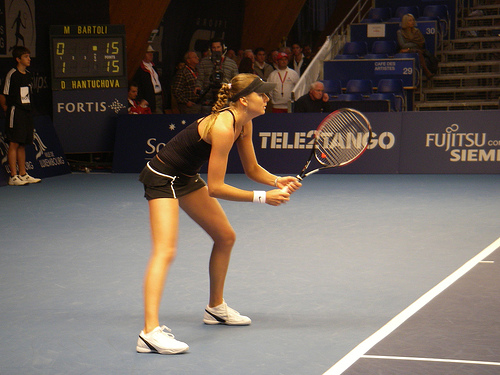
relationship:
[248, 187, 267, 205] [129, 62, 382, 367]
wrist band on player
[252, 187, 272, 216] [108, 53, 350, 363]
wrist band on player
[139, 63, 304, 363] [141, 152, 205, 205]
woman wearing shorts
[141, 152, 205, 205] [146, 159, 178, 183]
shorts with stripe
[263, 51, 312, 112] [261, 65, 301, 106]
man wearing sweater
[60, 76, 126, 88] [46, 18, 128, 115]
writing on scoreboard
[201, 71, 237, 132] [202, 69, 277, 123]
braid in hair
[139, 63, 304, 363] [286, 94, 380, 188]
woman holding tennis racket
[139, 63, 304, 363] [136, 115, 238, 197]
woman wearing uniform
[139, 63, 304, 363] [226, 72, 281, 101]
woman wearing visor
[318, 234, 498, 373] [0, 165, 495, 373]
line on court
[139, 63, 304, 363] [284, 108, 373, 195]
woman holding tennis racket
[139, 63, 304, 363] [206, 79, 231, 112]
woman with ponytail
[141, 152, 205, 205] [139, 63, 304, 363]
shorts on woman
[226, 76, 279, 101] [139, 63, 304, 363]
sunvisor on woman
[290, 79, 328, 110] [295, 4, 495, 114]
man sitting in stands